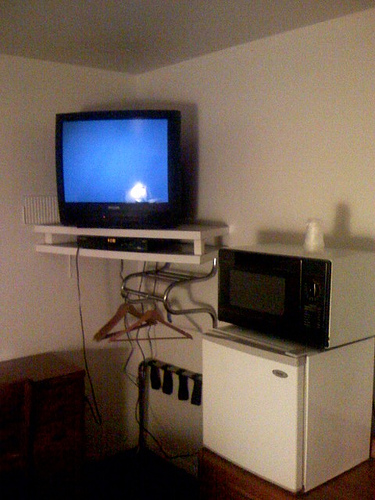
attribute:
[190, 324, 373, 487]
refrigerator — white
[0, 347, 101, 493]
desk — wooden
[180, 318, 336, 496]
refrigerator — small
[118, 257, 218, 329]
bar — chrome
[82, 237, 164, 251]
dvd — black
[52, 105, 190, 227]
television — black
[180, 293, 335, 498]
refrigerator — white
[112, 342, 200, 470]
chair — metal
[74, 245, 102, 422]
cable — black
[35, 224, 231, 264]
shelf — white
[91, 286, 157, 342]
hanger — wooden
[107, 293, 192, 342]
hanger — wooden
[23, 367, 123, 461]
chair — wooden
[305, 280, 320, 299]
dial knob — black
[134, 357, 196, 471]
bar — chrome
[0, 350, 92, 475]
dresser — wood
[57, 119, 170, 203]
screen — blue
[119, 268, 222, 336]
rack — metal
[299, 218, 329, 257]
cups — stacked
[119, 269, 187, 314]
rail — metal